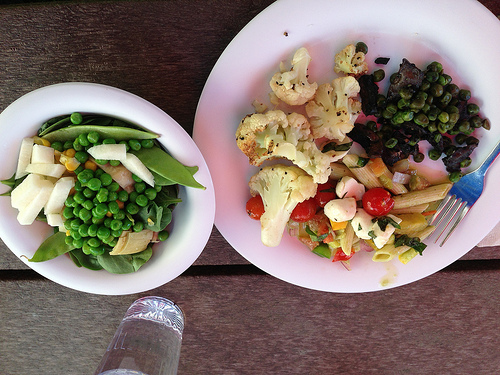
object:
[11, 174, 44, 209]
cheese chunks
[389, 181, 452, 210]
pasta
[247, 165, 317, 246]
cauliflower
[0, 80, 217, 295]
bowl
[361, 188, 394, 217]
tomato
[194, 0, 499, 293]
plate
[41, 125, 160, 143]
snap pea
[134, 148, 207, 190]
snap pea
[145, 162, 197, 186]
snap pea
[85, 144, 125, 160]
vegetables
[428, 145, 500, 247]
fork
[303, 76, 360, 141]
food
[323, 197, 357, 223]
cheese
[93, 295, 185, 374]
glass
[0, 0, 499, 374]
table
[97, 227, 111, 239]
peas